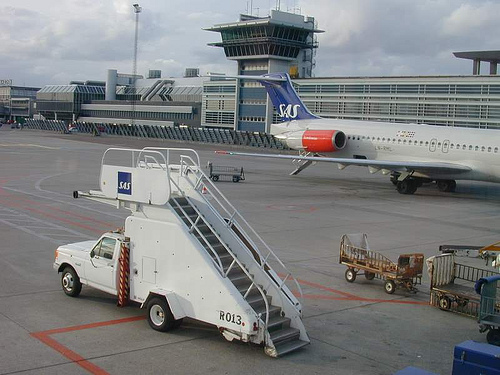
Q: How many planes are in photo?
A: One.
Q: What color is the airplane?
A: White.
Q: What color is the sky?
A: Blue.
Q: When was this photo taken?
A: In the daytime.